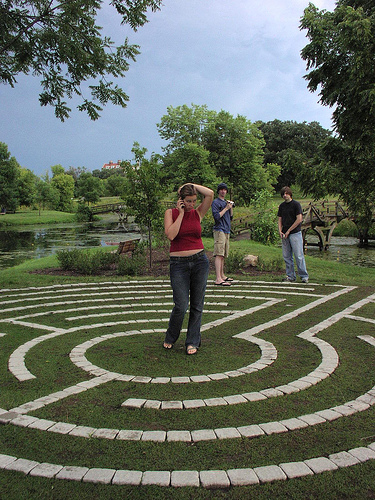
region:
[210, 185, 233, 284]
woman in the center with a phone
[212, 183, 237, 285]
Man in a blue shirt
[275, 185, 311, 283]
man in a black t-shirt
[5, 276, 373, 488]
replica of a sundial on the ground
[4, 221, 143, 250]
A pond surrounds the park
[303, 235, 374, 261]
another part of the pond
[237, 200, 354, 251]
A wooden bridge across the pond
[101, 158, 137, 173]
roof of a house in the background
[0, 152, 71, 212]
trees in the background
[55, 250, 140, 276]
shrubs next to the bench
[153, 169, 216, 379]
woman standing in middle of maze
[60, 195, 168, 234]
arched bridge over stream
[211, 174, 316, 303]
two men standing on edge of maze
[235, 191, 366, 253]
wooden structure forming bridge over stream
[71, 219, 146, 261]
bench facing the stream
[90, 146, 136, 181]
building peeking over the tree tops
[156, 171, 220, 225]
woman on cellphone holding head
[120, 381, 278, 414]
maze made with square stones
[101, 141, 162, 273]
thin tree growing behind bench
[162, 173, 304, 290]
men looking at woman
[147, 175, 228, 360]
The girl is using a mobile phone.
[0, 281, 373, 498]
The girl is in the center of a maze.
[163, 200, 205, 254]
The girl wears a red top.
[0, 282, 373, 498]
The maze is made from stone squares.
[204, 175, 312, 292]
Two boys are looking at the girl.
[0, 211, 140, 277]
A pond is behind the maze.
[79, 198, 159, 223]
A bridge crosses over the pond.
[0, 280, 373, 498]
Grass grows under the stone maze.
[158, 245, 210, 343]
The girl is wearing jeans.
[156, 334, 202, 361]
The girl is wearing sandals.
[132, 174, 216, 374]
Girl on a cell phone.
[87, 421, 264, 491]
Flat rocks on grass.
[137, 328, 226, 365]
Summer sandals on feet.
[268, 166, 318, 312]
Man in black shirt.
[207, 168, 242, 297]
Man in blue shirt.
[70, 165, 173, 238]
A bridge over water.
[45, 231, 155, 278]
Wooden and metal bench by water.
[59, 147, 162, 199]
White mansion with red roof.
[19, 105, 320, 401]
Scene of people by the water.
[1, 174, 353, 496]
People standing on a maze.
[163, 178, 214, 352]
girl with a maroon top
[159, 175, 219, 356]
girl talking on phone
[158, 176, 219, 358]
girl with arm over her head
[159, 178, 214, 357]
girl wearing jeans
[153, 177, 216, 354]
girl wearing flip flops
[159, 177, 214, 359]
girl who solved circular maze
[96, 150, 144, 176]
house on the hill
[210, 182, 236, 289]
guy with a camera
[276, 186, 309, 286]
man in blue jeans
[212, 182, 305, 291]
two guys looking on